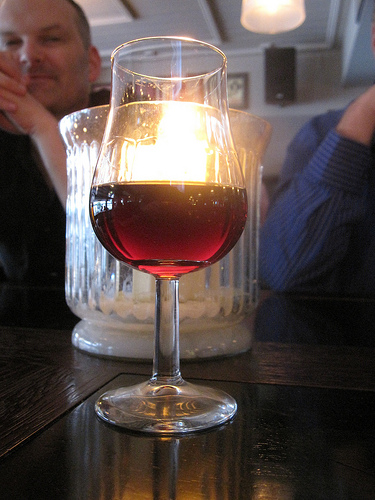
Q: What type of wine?
A: Red.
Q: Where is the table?
A: Under glass.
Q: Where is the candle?
A: Behind glass.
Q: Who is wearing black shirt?
A: Man on left.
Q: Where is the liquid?
A: Wine glass.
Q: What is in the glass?
A: Wine.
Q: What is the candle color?
A: White.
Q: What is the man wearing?
A: Blue shirt.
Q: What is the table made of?
A: Stained wood.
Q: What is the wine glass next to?
A: Candle.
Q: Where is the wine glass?
A: Top of table.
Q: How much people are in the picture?
A: Two.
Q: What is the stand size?
A: Tall.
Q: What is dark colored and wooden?
A: The table.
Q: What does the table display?
A: A reflection.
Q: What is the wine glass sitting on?
A: The table.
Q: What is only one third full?
A: The glass.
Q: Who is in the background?
A: Two men.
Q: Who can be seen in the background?
A: A man.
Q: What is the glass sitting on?
A: Table.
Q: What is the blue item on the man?
A: Shirt.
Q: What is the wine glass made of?
A: Glass.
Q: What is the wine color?
A: Red.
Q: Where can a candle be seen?
A: Behind the wine glass.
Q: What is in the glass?
A: Wine.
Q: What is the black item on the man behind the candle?
A: Shirt.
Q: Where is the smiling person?
A: Background.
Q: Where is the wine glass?
A: On the table.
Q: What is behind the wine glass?
A: A candle.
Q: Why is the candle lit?
A: Its dark.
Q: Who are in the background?
A: 2 men.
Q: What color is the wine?
A: Red.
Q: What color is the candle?
A: White.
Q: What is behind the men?
A: Ceiling and wall.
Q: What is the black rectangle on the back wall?
A: A speaker.